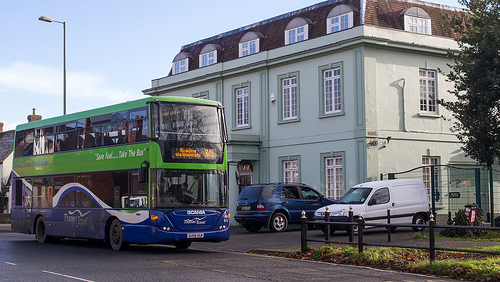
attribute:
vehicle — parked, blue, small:
[234, 181, 331, 231]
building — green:
[141, 0, 499, 226]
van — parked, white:
[312, 178, 431, 238]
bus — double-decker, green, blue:
[12, 96, 234, 254]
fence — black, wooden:
[299, 208, 500, 264]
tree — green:
[433, 1, 499, 174]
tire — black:
[269, 212, 287, 232]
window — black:
[150, 101, 223, 146]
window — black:
[154, 167, 229, 207]